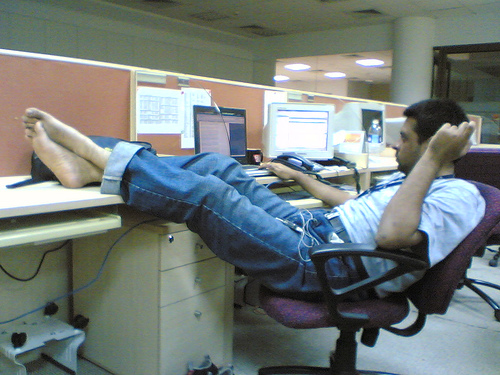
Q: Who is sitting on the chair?
A: The man.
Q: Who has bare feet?
A: The man.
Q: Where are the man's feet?
A: On the desk.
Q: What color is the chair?
A: Red and black.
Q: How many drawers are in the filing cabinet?
A: Three.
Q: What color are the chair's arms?
A: Black.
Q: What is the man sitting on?
A: The chair.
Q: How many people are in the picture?
A: One.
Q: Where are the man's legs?
A: Desk.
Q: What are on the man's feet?
A: Nothing.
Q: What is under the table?
A: Drawers.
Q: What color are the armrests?
A: Black.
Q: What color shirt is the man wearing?
A: White.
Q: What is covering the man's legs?
A: Jeans.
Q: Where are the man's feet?
A: Desk.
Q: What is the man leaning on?
A: Chair.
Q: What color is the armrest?
A: Black.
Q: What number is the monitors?
A: Three.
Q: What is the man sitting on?
A: A chair.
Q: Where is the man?
A: In an office.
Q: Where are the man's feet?
A: On the desk.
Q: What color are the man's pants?
A: Blue.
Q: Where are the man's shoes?
A: On the floor.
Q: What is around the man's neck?
A: A lanyard.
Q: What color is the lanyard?
A: Blue.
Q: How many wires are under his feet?
A: Two.